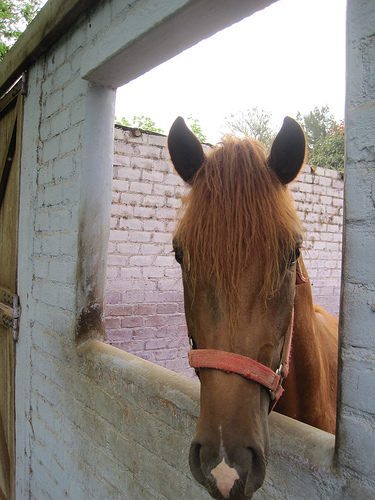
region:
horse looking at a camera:
[141, 101, 351, 498]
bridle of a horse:
[188, 327, 303, 401]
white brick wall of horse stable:
[29, 111, 79, 486]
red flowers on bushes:
[326, 123, 345, 141]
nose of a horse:
[187, 437, 271, 485]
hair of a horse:
[196, 160, 264, 291]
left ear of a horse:
[265, 104, 312, 187]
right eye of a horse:
[163, 230, 185, 269]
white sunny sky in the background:
[201, 34, 345, 67]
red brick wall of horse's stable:
[122, 138, 170, 342]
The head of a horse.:
[167, 117, 308, 498]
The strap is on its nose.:
[188, 342, 282, 400]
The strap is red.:
[187, 347, 279, 396]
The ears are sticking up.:
[166, 103, 204, 185]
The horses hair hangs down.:
[183, 139, 277, 290]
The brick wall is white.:
[18, 64, 89, 497]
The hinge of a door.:
[19, 70, 25, 97]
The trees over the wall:
[323, 121, 345, 168]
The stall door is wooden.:
[0, 77, 20, 498]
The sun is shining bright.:
[206, 56, 302, 107]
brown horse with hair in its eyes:
[152, 105, 317, 496]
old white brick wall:
[27, 65, 115, 493]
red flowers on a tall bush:
[314, 108, 350, 165]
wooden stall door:
[7, 110, 18, 371]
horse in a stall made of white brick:
[131, 111, 310, 492]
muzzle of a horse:
[188, 413, 272, 497]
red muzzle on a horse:
[180, 337, 297, 402]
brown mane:
[193, 133, 306, 296]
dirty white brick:
[116, 121, 167, 247]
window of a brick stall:
[66, 40, 372, 495]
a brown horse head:
[147, 121, 297, 490]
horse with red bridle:
[152, 130, 294, 416]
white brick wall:
[26, 368, 147, 492]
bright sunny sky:
[222, 42, 345, 99]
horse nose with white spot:
[184, 423, 259, 493]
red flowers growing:
[309, 118, 342, 164]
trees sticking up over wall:
[202, 105, 344, 163]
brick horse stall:
[110, 116, 189, 354]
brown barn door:
[0, 80, 18, 495]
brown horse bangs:
[162, 116, 310, 282]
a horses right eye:
[276, 236, 323, 275]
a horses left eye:
[161, 238, 211, 265]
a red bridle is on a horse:
[175, 302, 309, 385]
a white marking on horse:
[184, 417, 298, 498]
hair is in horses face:
[158, 127, 305, 295]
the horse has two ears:
[157, 111, 323, 189]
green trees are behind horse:
[110, 97, 346, 183]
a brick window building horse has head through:
[18, 383, 373, 499]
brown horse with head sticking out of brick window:
[3, 0, 344, 499]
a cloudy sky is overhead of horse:
[118, 0, 339, 156]